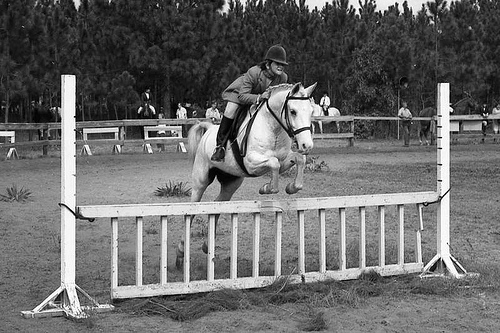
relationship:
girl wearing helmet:
[210, 44, 287, 163] [261, 44, 290, 67]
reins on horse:
[237, 89, 312, 160] [171, 80, 317, 272]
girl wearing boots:
[210, 44, 287, 163] [208, 114, 235, 159]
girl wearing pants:
[210, 44, 287, 163] [222, 100, 238, 120]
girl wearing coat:
[210, 44, 287, 163] [221, 65, 289, 106]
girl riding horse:
[210, 44, 287, 163] [171, 80, 317, 272]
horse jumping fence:
[171, 80, 317, 272] [20, 72, 480, 326]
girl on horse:
[210, 44, 287, 163] [171, 80, 317, 272]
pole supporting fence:
[415, 80, 480, 283] [20, 72, 480, 326]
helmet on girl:
[261, 44, 290, 67] [210, 44, 287, 163]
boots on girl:
[208, 114, 235, 159] [210, 44, 287, 163]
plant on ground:
[154, 179, 193, 200] [0, 134, 499, 332]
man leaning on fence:
[395, 98, 415, 148] [1, 113, 499, 162]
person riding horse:
[134, 85, 156, 116] [139, 102, 158, 153]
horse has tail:
[171, 80, 317, 272] [185, 119, 213, 165]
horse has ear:
[171, 80, 317, 272] [292, 83, 303, 99]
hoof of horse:
[258, 184, 269, 195] [171, 80, 317, 272]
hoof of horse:
[287, 182, 294, 196] [171, 80, 317, 272]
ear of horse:
[304, 83, 319, 103] [171, 80, 317, 272]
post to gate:
[23, 74, 113, 320] [14, 71, 479, 320]